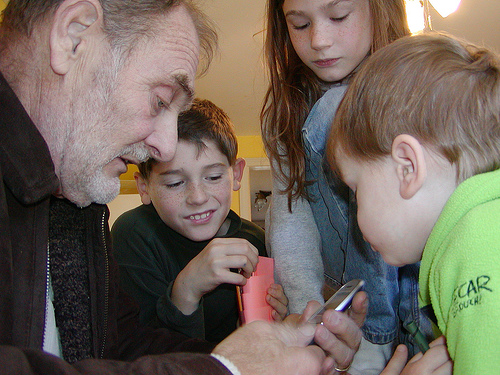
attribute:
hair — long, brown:
[259, 2, 423, 213]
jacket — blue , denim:
[332, 192, 432, 347]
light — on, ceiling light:
[405, 0, 477, 25]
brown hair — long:
[262, 0, 319, 208]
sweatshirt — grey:
[266, 105, 325, 319]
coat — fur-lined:
[3, 87, 213, 372]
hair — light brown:
[324, 23, 499, 264]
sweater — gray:
[227, 86, 347, 315]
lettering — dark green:
[448, 272, 493, 315]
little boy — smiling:
[94, 92, 279, 363]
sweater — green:
[413, 162, 498, 371]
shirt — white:
[35, 253, 72, 356]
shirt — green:
[420, 170, 497, 372]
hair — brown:
[124, 87, 237, 179]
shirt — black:
[108, 199, 268, 367]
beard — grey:
[72, 79, 134, 205]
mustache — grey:
[123, 141, 153, 162]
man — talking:
[0, 1, 370, 373]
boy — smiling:
[110, 95, 265, 342]